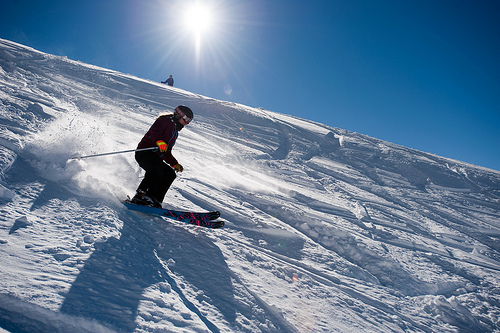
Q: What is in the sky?
A: A sun.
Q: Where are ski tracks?
A: On the snow.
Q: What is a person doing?
A: Skiing.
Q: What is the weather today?
A: Clear and sunny.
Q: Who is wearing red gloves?
A: The skier.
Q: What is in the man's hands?
A: Poles.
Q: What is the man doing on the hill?
A: Skiing.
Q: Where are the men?
A: Ski area.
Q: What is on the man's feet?
A: Skis.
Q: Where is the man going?
A: Downhill.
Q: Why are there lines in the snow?
A: Ski tracks.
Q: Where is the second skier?
A: Top of hill.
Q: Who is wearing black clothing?
A: The skier.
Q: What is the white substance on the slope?
A: Snow.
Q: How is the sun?
A: Bright.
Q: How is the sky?
A: Clear.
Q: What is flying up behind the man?
A: Snow.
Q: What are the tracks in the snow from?
A: Skis.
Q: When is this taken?
A: During the day.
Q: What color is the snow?
A: White.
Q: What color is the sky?
A: Blue.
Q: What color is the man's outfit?
A: Black.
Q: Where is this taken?
A: On a mountain.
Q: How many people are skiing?
A: One.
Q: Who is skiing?
A: The man.